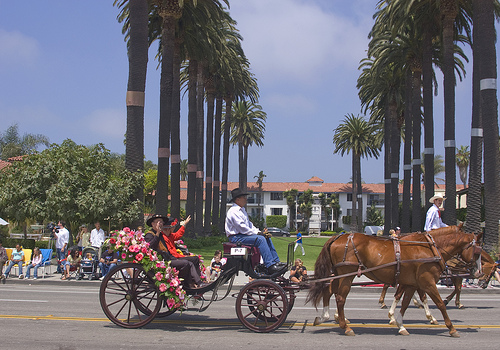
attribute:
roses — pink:
[102, 220, 191, 309]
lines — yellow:
[2, 309, 498, 334]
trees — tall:
[327, 0, 497, 250]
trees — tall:
[103, 0, 264, 240]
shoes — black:
[264, 261, 294, 279]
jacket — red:
[160, 222, 188, 262]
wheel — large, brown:
[94, 258, 166, 328]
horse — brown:
[314, 236, 494, 339]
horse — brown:
[334, 228, 497, 330]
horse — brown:
[308, 225, 483, 338]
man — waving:
[143, 209, 207, 294]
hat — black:
[228, 185, 253, 206]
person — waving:
[163, 214, 206, 282]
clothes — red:
[164, 219, 189, 259]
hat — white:
[427, 189, 447, 203]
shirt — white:
[423, 206, 448, 231]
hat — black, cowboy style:
[227, 186, 252, 202]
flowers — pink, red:
[101, 228, 194, 311]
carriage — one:
[99, 210, 296, 332]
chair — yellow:
[118, 207, 210, 331]